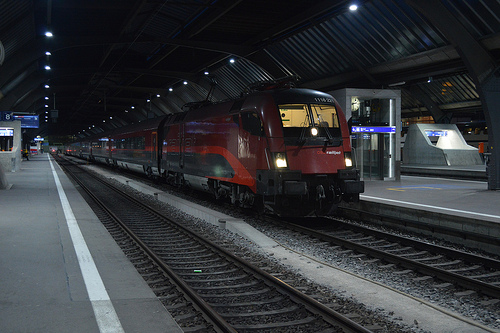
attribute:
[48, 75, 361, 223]
train — long, red, black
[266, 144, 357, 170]
headlights — square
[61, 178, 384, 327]
tracks — black, brown, long, beside each other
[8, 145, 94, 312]
walkway — long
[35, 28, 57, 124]
lights — here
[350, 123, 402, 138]
sign — purple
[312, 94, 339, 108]
numbers — white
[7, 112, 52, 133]
sign — hanging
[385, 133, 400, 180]
pole — steel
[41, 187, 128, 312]
line — white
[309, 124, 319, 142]
light — round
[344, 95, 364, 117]
clock — white